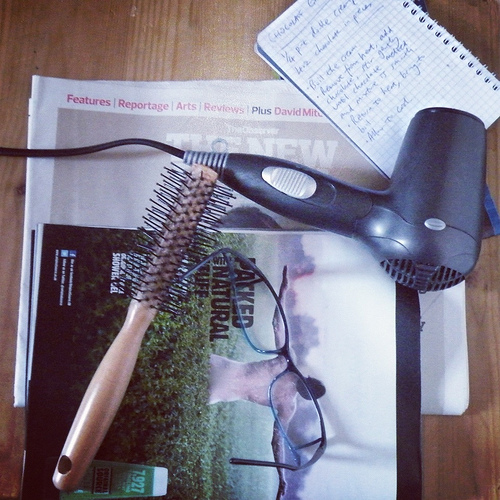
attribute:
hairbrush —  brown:
[111, 163, 266, 281]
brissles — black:
[135, 167, 219, 285]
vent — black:
[375, 253, 475, 296]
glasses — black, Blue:
[168, 245, 330, 475]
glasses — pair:
[182, 243, 327, 473]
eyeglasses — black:
[164, 248, 328, 488]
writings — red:
[64, 90, 324, 119]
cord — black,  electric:
[2, 131, 178, 159]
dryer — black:
[185, 56, 487, 271]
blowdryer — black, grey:
[178, 105, 485, 295]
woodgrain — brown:
[438, 398, 486, 483]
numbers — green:
[129, 467, 146, 497]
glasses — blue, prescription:
[202, 240, 337, 499]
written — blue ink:
[329, 65, 399, 147]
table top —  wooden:
[54, 50, 107, 116]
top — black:
[382, 108, 483, 246]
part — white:
[301, 235, 402, 498]